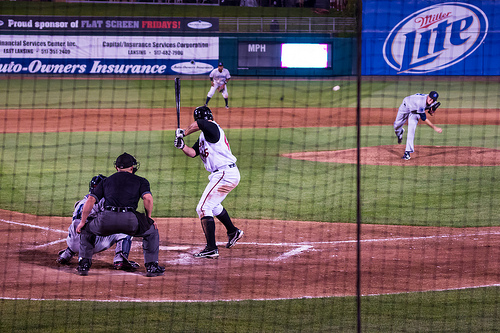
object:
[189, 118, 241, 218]
uniform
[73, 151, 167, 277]
umpire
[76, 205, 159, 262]
grey pants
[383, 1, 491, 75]
lite sign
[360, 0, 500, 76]
advertisement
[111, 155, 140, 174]
cap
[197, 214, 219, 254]
sock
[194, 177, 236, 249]
leg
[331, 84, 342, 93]
baseball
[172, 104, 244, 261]
batter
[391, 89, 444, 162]
pitcher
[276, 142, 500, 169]
mound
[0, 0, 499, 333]
net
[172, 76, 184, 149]
black bat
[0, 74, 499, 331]
baseball field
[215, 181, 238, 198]
dirt